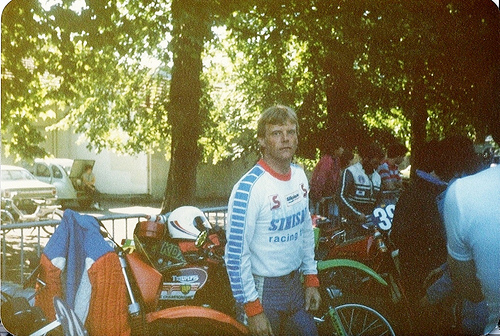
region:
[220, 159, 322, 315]
A long sleeve shirt on a man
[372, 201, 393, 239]
A white number three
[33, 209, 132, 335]
A jacket on a motorcycle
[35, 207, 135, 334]
A red, white, and blue jacket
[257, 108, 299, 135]
Short hair on a man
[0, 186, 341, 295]
A metal barricade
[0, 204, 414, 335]
Parked motorcycles along the barrier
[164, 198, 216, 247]
A white helmet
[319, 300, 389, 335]
Metal spokes on a tire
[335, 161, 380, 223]
A black and white jacket on a man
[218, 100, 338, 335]
A man is standing in front of a motorcycle.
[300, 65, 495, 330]
A group of people are around some motorcycles.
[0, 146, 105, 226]
Cars are parked in the background.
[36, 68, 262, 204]
A building is in the background.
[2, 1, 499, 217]
Trees are in the background.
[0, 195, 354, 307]
A metal fence is behind the motorcycles.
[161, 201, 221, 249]
A striped helmet is sitting on one of the motorcycles.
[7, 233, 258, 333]
One of the motorcycles has an orange front.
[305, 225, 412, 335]
Another of the motorcycles has a green lime front.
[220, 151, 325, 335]
A man in front is wearing a white, blue, and red outfit.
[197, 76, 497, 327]
A group of people are here for an event.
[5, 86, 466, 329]
The people here are surrounded by motorcycles.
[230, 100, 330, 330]
The man is wearing a blue, white, and red shirt.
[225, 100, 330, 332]
The man's shirt has writing on it.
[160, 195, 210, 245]
A white motorcycle helmet.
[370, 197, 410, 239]
A racing number.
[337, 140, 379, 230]
A man examining a bicycle.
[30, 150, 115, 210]
A person sitting in the back of a car.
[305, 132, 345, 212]
The man is leaning on the barrier.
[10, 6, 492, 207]
The area is shaded by trees.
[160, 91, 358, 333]
bike racer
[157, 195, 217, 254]
white racing helmet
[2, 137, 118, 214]
vintage city cars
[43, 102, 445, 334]
preparing for race day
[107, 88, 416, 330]
man preparing for bike racing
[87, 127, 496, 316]
vintage bike races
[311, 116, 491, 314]
men preparing for a bike race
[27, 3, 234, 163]
sunlight shining through a large tree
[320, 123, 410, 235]
vintage beared men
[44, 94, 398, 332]
motorcycle races in the 1970s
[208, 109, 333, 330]
a man wearing a sweatshirt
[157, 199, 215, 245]
a white motorcycle helmet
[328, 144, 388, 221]
a man in a black and white jacket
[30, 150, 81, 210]
a white car in the driveway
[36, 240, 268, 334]
a red motorcycle with a jacket on it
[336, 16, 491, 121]
a group of leafy trees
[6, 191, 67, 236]
a little white motorcycle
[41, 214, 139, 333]
a colorful motorcycle jacket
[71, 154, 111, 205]
a person sitting in a car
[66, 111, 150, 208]
a garage door for a house